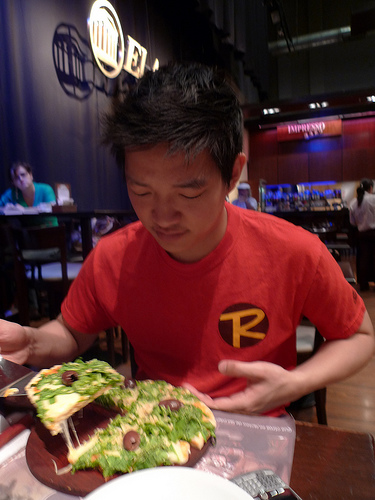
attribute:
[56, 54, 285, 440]
person — sitting, standing, wearing, ready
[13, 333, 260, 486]
pizza — kept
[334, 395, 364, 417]
floor — wooden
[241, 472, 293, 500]
phone — part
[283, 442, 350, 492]
table — part, plate, behind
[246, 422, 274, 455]
cover — part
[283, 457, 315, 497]
wood — part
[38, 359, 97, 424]
food — part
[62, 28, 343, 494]
man — wearing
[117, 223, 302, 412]
shirt — red, graphic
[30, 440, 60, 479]
board — wooden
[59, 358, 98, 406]
stone — food